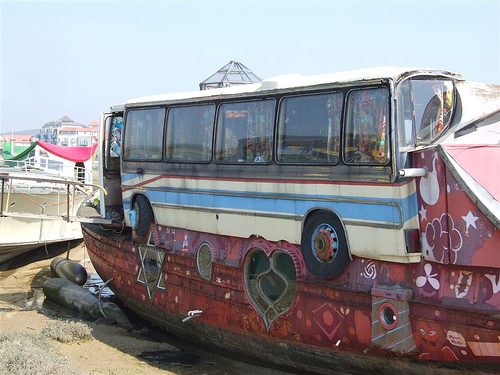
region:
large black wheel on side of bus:
[280, 204, 358, 289]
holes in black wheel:
[303, 217, 344, 271]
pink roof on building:
[24, 131, 101, 168]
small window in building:
[32, 149, 64, 171]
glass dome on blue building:
[198, 57, 280, 94]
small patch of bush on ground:
[35, 313, 99, 350]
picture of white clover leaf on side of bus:
[405, 260, 462, 296]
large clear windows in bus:
[207, 92, 367, 170]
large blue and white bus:
[79, 67, 495, 264]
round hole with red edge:
[366, 293, 417, 357]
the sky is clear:
[1, 5, 487, 85]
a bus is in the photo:
[81, 94, 498, 266]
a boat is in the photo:
[56, 175, 498, 364]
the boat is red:
[73, 216, 496, 373]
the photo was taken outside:
[1, 10, 498, 374]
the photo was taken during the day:
[5, 5, 499, 370]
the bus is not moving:
[64, 58, 496, 287]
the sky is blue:
[7, 2, 498, 75]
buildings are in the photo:
[4, 109, 124, 231]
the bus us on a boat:
[84, 73, 499, 373]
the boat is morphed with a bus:
[83, 68, 499, 373]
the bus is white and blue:
[96, 68, 460, 262]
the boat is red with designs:
[81, 145, 499, 373]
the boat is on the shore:
[1, 245, 289, 374]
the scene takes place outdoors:
[0, 0, 499, 372]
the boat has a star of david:
[136, 223, 166, 294]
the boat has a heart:
[241, 245, 297, 332]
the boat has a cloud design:
[424, 212, 462, 264]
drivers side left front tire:
[126, 190, 157, 235]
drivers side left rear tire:
[298, 202, 351, 280]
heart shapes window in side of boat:
[237, 238, 302, 338]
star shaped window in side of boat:
[127, 227, 170, 302]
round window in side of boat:
[368, 290, 411, 346]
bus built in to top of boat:
[98, 81, 455, 273]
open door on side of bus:
[98, 103, 129, 229]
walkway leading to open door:
[3, 169, 113, 229]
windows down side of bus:
[124, 79, 412, 179]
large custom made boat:
[78, 82, 495, 370]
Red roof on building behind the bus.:
[40, 138, 100, 160]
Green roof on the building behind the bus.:
[5, 143, 39, 157]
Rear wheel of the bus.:
[122, 191, 150, 231]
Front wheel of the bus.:
[301, 212, 341, 269]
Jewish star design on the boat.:
[134, 228, 171, 310]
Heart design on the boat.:
[233, 242, 298, 336]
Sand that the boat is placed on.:
[3, 275, 293, 373]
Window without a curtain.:
[283, 97, 338, 164]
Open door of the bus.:
[99, 112, 121, 223]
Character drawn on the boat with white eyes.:
[417, 317, 452, 367]